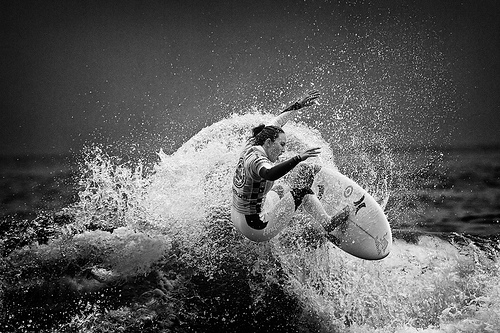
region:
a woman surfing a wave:
[168, 87, 395, 267]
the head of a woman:
[246, 118, 286, 163]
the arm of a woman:
[263, 145, 325, 182]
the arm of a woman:
[263, 87, 325, 129]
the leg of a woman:
[273, 190, 358, 236]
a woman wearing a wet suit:
[207, 88, 347, 255]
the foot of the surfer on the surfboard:
[323, 200, 366, 247]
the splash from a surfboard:
[52, 100, 219, 276]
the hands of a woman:
[293, 83, 326, 170]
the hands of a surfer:
[288, 82, 333, 174]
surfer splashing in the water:
[194, 85, 426, 273]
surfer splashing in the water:
[212, 85, 397, 273]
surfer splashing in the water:
[208, 88, 410, 292]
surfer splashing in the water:
[186, 73, 413, 277]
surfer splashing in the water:
[182, 55, 389, 270]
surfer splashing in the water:
[211, 103, 388, 270]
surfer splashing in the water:
[204, 71, 384, 273]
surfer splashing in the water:
[206, 75, 393, 284]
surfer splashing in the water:
[225, 88, 395, 293]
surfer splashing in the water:
[250, 112, 395, 267]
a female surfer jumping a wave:
[144, 88, 421, 264]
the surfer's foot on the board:
[313, 196, 366, 241]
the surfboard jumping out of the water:
[308, 159, 415, 296]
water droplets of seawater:
[336, 38, 450, 161]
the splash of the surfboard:
[76, 140, 211, 277]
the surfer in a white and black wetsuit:
[225, 94, 355, 251]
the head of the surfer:
[250, 123, 292, 168]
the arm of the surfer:
[268, 142, 335, 188]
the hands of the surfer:
[292, 83, 329, 168]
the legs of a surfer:
[266, 177, 349, 245]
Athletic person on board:
[230, 93, 317, 233]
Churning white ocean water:
[338, 271, 378, 308]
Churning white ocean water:
[436, 255, 476, 310]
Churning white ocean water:
[87, 231, 147, 259]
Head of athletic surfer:
[250, 121, 290, 161]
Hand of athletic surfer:
[298, 141, 320, 161]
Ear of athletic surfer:
[264, 135, 270, 147]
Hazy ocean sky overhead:
[87, 59, 149, 94]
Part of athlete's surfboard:
[355, 222, 379, 248]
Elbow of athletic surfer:
[263, 168, 283, 183]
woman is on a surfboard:
[231, 88, 393, 260]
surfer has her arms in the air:
[231, 88, 351, 242]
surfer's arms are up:
[230, 89, 347, 244]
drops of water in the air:
[70, 0, 470, 191]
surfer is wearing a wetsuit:
[231, 87, 351, 242]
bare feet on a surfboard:
[325, 204, 351, 233]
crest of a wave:
[3, 216, 499, 329]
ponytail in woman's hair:
[248, 123, 266, 139]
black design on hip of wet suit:
[242, 212, 269, 231]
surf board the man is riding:
[273, 156, 393, 260]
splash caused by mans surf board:
[5, 33, 497, 329]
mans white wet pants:
[227, 185, 332, 244]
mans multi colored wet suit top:
[226, 99, 304, 216]